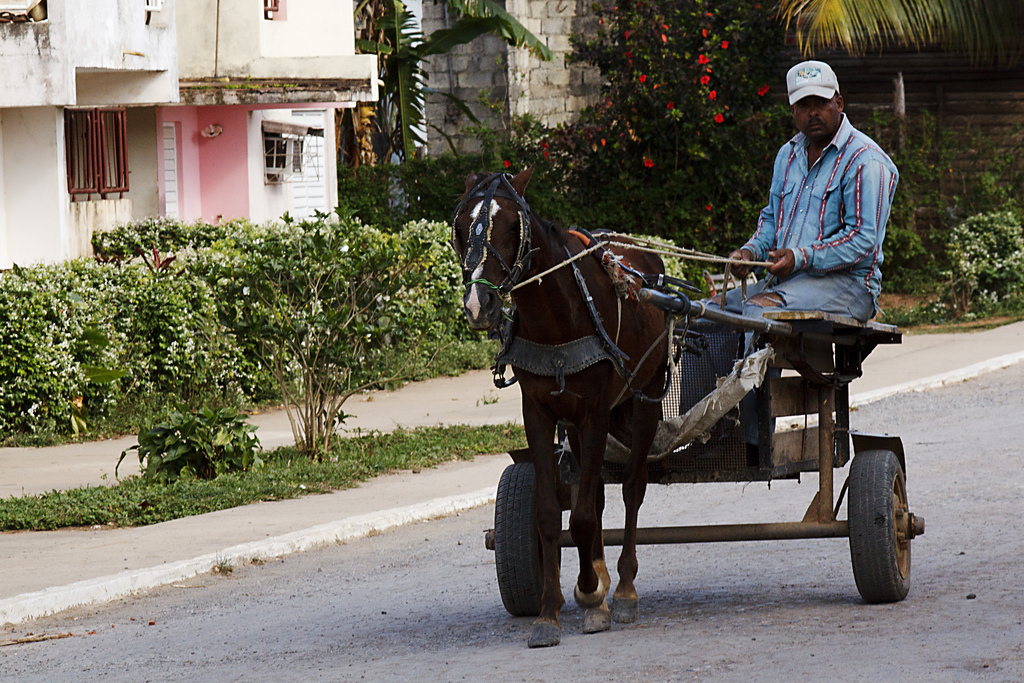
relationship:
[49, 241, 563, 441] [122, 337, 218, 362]
bush has flowers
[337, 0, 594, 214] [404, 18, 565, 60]
tree has leaf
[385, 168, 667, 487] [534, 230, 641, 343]
horse has reins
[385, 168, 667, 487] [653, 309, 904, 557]
horse has cart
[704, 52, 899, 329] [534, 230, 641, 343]
man holding reins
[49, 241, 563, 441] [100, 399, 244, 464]
bush was trimmed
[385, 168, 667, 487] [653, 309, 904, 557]
horse pulling cart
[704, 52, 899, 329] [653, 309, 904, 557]
man driving cart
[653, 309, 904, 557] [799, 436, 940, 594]
cart has wheels